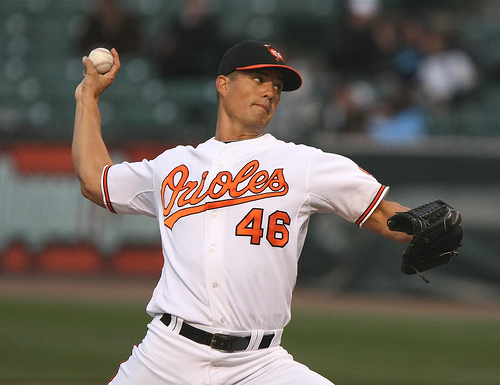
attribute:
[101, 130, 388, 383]
pitcher's unifrom — white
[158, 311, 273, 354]
belt — black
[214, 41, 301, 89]
hat — black and red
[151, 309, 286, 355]
belt — black, thin, leather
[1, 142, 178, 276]
advertisement — orange, white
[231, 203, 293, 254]
46 — number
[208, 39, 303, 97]
hat — black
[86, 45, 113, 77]
baseball — diamond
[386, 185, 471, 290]
glove — black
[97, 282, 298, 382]
pants — white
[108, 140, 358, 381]
jersey — orange, white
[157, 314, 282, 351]
belt — black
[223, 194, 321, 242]
number 46 — pictured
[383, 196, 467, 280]
baseball glove — black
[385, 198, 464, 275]
glove — baseball glove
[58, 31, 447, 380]
pitcher — right handed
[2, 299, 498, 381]
grass — green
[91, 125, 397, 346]
jersey — white and orange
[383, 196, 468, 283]
glove — black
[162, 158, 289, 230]
writing — orange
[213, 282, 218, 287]
button — white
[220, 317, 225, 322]
button — white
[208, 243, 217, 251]
button — white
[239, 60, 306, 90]
brim — orange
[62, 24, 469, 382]
player — baseball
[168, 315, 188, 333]
belt loops — white